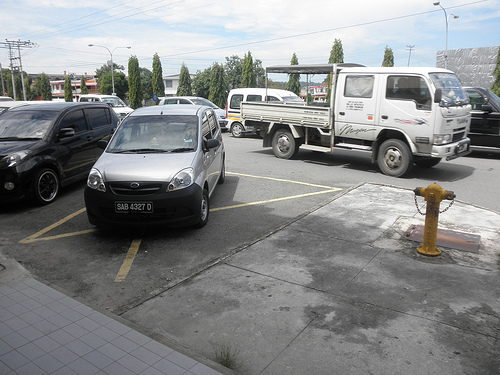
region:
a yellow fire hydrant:
[397, 179, 459, 260]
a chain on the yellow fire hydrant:
[407, 189, 458, 219]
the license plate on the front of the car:
[110, 198, 159, 219]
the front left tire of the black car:
[30, 164, 65, 205]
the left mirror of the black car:
[54, 125, 79, 141]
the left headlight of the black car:
[0, 142, 37, 174]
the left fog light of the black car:
[0, 175, 21, 192]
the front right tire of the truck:
[372, 134, 414, 181]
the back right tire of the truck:
[267, 124, 296, 159]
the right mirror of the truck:
[430, 84, 443, 106]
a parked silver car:
[81, 101, 229, 231]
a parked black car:
[1, 101, 116, 206]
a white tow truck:
[239, 64, 471, 175]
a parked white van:
[224, 87, 307, 137]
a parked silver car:
[157, 91, 227, 132]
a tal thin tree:
[149, 50, 164, 102]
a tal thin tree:
[125, 54, 141, 107]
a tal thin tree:
[175, 64, 191, 96]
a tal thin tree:
[242, 50, 254, 87]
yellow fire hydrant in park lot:
[407, 173, 452, 260]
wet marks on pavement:
[268, 202, 490, 374]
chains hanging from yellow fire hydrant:
[412, 195, 450, 217]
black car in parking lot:
[2, 92, 108, 215]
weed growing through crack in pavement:
[205, 344, 241, 374]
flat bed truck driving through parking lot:
[245, 53, 462, 168]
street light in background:
[432, 3, 453, 60]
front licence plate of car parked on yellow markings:
[110, 194, 157, 220]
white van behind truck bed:
[223, 75, 300, 134]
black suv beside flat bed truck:
[452, 75, 499, 142]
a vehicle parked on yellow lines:
[78, 101, 243, 271]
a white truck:
[242, 66, 462, 153]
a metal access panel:
[403, 227, 483, 247]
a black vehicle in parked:
[2, 92, 112, 211]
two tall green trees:
[115, 47, 178, 105]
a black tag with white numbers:
[109, 199, 163, 216]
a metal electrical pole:
[0, 26, 44, 88]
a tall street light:
[83, 29, 138, 97]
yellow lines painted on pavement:
[228, 174, 335, 225]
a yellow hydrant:
[408, 174, 463, 256]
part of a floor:
[283, 246, 310, 291]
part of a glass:
[218, 328, 237, 368]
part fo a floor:
[317, 317, 344, 362]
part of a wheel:
[199, 193, 214, 226]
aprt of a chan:
[436, 213, 442, 231]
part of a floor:
[338, 313, 371, 362]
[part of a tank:
[412, 216, 432, 282]